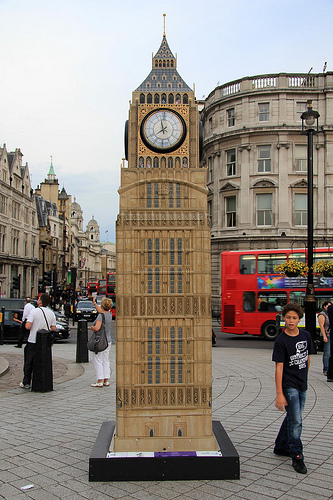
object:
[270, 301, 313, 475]
person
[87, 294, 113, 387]
person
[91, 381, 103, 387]
white shoes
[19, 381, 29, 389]
white shoes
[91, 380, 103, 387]
shoes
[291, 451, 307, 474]
shoes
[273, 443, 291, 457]
shoes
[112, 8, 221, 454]
statue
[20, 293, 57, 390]
man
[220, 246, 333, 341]
double decker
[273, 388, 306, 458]
blue jeans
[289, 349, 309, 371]
writing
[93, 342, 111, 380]
pants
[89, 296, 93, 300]
smartphone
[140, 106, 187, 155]
clock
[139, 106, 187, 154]
face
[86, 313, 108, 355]
handbag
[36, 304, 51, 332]
strap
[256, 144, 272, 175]
window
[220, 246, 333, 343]
bus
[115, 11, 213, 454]
clock tower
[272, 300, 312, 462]
boy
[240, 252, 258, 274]
window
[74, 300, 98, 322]
car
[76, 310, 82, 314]
headlights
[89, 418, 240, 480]
base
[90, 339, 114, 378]
white pants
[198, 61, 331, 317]
curved building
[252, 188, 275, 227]
window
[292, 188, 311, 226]
window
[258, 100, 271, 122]
window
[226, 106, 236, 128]
window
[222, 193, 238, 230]
window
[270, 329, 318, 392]
shirt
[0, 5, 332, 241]
sky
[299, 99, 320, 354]
light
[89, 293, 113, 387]
woman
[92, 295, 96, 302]
hand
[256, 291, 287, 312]
window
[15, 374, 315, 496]
pavement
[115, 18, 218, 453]
tower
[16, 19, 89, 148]
light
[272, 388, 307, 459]
jeans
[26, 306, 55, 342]
shirt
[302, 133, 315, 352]
post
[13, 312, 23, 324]
person